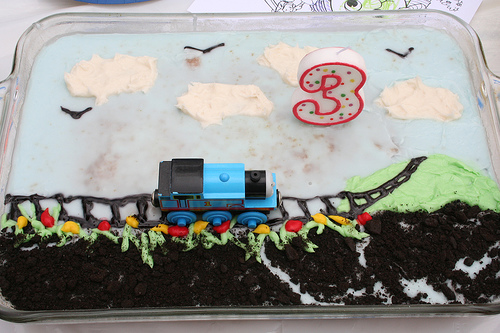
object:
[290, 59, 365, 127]
outline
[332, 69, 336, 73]
dot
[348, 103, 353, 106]
dot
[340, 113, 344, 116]
dot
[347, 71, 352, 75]
dot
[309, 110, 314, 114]
dot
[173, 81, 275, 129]
icing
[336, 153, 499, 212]
grass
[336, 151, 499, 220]
icing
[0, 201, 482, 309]
dirt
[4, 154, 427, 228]
icing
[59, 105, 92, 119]
icing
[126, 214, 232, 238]
icing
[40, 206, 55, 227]
flower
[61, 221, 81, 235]
flower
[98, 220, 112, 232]
flower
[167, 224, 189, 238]
flower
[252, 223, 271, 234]
flower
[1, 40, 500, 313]
cake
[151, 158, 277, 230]
train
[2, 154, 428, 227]
train track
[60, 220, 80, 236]
icing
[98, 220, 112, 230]
icing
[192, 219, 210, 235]
icing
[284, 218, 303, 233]
icing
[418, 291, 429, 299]
oreo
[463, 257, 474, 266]
oreo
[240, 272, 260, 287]
oreo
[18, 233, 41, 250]
oreo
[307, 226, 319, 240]
oreo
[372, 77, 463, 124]
cloud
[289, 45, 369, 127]
number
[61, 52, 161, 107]
cloud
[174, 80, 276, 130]
cloud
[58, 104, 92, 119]
bird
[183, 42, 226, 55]
bird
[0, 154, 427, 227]
track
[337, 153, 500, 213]
mountain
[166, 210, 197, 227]
wheel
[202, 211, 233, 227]
wheel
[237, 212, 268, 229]
wheel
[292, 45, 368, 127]
candle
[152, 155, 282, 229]
tank engine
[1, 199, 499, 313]
cookie crumbs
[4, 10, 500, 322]
cake pan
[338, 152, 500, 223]
frosting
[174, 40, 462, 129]
frosting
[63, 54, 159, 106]
frosting